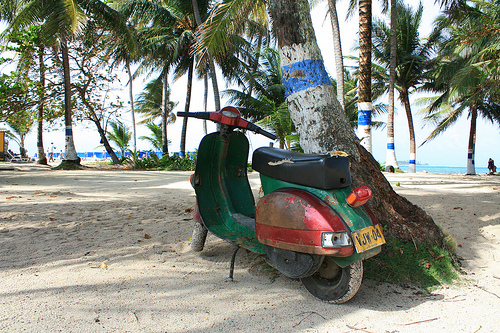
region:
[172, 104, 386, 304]
Scooter parked next to the tree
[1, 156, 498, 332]
White sand on the beach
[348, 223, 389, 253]
Yellow plate number on the scooter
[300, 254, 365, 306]
Rear wheel of the scooter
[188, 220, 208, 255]
Front wheel of the scooter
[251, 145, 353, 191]
Black seat of the scooter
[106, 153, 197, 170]
Green shurb on the beach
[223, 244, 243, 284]
Center stand of the scooter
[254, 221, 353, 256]
Exhaust of the scooter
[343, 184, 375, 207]
Rear light of the scooter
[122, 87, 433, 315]
green and red bike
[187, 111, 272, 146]
black handles on bike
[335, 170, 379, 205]
red light on tail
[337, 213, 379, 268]
yellow and black license plate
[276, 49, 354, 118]
blue stripe on tree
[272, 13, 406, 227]
brown white and blue tree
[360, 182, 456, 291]
green grass at base of tree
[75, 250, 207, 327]
sand is off white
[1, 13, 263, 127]
white tropical trees in background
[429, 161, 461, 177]
blue water far away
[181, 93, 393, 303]
motorized bike in sand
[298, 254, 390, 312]
rear tire of motorized bike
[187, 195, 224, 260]
front tire of motorized bike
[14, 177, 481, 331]
sand on the beach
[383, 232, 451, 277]
patch of green grass near bike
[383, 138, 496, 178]
water near the sand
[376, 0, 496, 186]
trees in the sand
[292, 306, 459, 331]
twigs in the sand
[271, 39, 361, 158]
paint on trunk of tree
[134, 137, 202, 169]
patch of grass near tree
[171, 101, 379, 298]
a scooter is on the sand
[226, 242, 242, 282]
the scooter has the kickstand down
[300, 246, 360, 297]
the wheel is filled with dirt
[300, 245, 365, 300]
the wheel is made of rubber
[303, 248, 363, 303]
the wheel is black in color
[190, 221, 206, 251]
the wheel is black in color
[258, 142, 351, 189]
the seat is made of plastic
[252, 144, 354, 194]
the seat is black in color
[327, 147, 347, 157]
the seat is torn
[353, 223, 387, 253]
the license plate is made of metal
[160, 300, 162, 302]
part of a shade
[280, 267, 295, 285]
edge of a weel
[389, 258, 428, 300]
part of a grass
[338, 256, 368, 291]
part of a wheell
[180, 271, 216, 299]
part of a shade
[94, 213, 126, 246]
part of a shade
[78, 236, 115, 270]
part of a shade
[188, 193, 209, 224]
ede of a bike